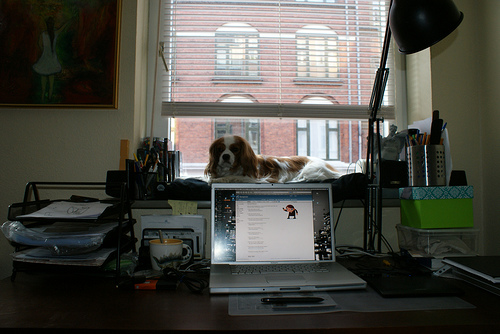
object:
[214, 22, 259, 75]
window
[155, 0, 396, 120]
blinds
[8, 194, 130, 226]
tray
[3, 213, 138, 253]
tray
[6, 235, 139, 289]
tray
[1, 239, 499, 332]
desk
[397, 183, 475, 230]
box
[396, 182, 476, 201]
lid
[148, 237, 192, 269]
cup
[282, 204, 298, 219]
character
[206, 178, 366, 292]
laptop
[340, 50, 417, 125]
ground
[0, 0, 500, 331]
room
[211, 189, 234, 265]
icons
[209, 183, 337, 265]
desktop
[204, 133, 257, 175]
head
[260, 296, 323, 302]
pen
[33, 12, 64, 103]
girl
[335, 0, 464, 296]
desk lamp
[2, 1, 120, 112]
picture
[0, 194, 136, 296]
organizer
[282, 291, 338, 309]
paper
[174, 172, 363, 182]
seal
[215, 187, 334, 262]
screen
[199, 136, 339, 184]
dog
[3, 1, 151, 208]
wall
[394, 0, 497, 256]
wall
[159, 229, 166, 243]
pen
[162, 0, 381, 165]
building